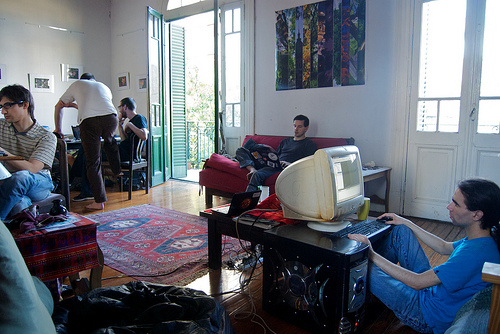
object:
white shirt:
[61, 79, 117, 123]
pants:
[76, 114, 120, 205]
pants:
[232, 142, 278, 193]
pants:
[366, 225, 440, 333]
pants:
[0, 168, 54, 222]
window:
[218, 5, 241, 124]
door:
[170, 24, 189, 180]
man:
[348, 177, 500, 327]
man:
[115, 96, 149, 164]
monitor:
[273, 143, 367, 234]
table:
[361, 156, 395, 216]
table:
[50, 127, 153, 214]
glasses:
[0, 100, 23, 113]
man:
[0, 83, 60, 247]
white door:
[458, 2, 498, 224]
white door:
[383, 0, 478, 226]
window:
[471, 0, 499, 134]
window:
[407, 0, 471, 132]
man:
[235, 114, 321, 222]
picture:
[24, 71, 56, 96]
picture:
[135, 75, 150, 91]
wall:
[1, 2, 500, 224]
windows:
[411, 0, 498, 139]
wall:
[54, 33, 122, 66]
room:
[0, 10, 500, 334]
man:
[51, 66, 122, 212]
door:
[154, 0, 262, 189]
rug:
[87, 202, 252, 284]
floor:
[55, 171, 498, 332]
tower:
[243, 220, 369, 318]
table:
[194, 200, 399, 317]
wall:
[254, 0, 394, 209]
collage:
[271, 0, 367, 92]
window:
[147, 17, 160, 105]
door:
[141, 4, 175, 188]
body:
[59, 78, 122, 203]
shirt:
[0, 118, 58, 181]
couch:
[193, 134, 382, 221]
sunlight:
[421, 46, 453, 91]